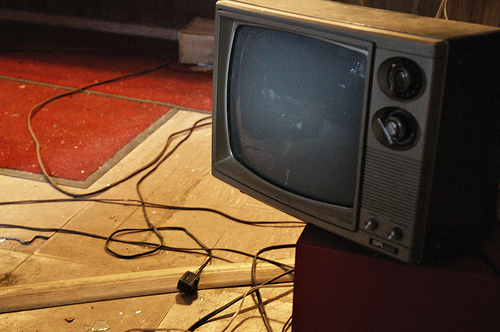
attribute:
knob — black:
[379, 63, 414, 95]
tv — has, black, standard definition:
[211, 0, 497, 265]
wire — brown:
[2, 42, 306, 329]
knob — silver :
[360, 218, 377, 235]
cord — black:
[23, 56, 224, 301]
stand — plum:
[289, 212, 497, 327]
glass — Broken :
[81, 296, 150, 328]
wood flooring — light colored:
[0, 108, 305, 328]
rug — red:
[0, 89, 181, 174]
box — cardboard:
[170, 10, 228, 70]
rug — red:
[18, 63, 197, 220]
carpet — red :
[0, 72, 177, 191]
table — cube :
[290, 220, 495, 328]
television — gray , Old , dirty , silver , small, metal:
[208, 1, 498, 262]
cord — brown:
[102, 113, 215, 293]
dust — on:
[314, 4, 456, 44]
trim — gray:
[69, 96, 174, 196]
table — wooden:
[272, 215, 494, 330]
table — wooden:
[270, 229, 498, 322]